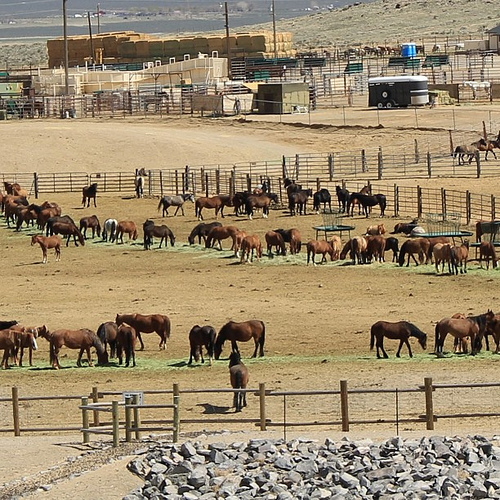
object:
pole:
[11, 386, 20, 436]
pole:
[172, 382, 179, 442]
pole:
[258, 383, 265, 430]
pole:
[339, 379, 349, 432]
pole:
[423, 377, 433, 430]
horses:
[51, 222, 87, 247]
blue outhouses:
[401, 42, 416, 59]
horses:
[433, 314, 479, 360]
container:
[367, 75, 430, 110]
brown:
[224, 325, 251, 338]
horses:
[143, 224, 176, 250]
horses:
[231, 191, 264, 215]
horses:
[432, 240, 454, 272]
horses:
[329, 239, 343, 261]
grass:
[1, 351, 498, 369]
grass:
[4, 211, 498, 278]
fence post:
[424, 376, 435, 431]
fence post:
[339, 379, 350, 431]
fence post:
[257, 383, 267, 431]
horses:
[480, 242, 500, 268]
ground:
[0, 105, 499, 435]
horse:
[102, 218, 118, 243]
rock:
[180, 440, 195, 455]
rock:
[257, 442, 274, 452]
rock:
[207, 450, 225, 465]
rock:
[339, 472, 359, 489]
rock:
[354, 447, 370, 454]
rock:
[432, 440, 455, 456]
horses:
[398, 237, 424, 270]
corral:
[0, 95, 499, 419]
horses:
[232, 234, 245, 256]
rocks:
[125, 462, 142, 474]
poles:
[62, 0, 70, 88]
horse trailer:
[367, 75, 429, 110]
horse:
[350, 235, 368, 263]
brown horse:
[114, 220, 139, 243]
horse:
[371, 321, 426, 359]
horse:
[188, 324, 215, 365]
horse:
[31, 233, 62, 262]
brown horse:
[306, 240, 336, 266]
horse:
[351, 190, 387, 216]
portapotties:
[402, 42, 415, 54]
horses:
[237, 192, 279, 219]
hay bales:
[44, 30, 294, 119]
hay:
[47, 27, 296, 67]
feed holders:
[312, 208, 354, 242]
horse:
[203, 320, 268, 360]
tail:
[110, 223, 116, 239]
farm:
[1, 0, 499, 498]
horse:
[226, 351, 250, 409]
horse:
[115, 313, 172, 350]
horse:
[48, 328, 109, 368]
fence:
[0, 105, 499, 445]